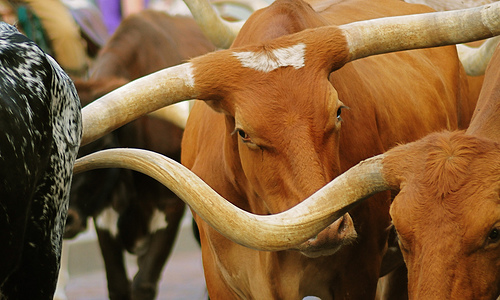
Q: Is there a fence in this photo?
A: No, there are no fences.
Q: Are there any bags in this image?
A: No, there are no bags.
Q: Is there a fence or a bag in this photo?
A: No, there are no bags or fences.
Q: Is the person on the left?
A: Yes, the person is on the left of the image.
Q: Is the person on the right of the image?
A: No, the person is on the left of the image.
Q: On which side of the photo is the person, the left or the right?
A: The person is on the left of the image.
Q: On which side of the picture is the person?
A: The person is on the left of the image.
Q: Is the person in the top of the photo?
A: Yes, the person is in the top of the image.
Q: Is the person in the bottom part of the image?
A: No, the person is in the top of the image.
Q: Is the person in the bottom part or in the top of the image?
A: The person is in the top of the image.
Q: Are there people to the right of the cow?
A: No, the person is to the left of the cow.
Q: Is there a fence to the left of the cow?
A: No, there is a person to the left of the cow.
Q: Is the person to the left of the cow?
A: Yes, the person is to the left of the cow.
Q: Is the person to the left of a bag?
A: No, the person is to the left of the cow.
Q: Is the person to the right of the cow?
A: No, the person is to the left of the cow.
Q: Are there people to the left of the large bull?
A: Yes, there is a person to the left of the bull.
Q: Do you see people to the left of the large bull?
A: Yes, there is a person to the left of the bull.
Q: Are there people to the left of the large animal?
A: Yes, there is a person to the left of the bull.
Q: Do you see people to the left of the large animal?
A: Yes, there is a person to the left of the bull.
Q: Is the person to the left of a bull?
A: Yes, the person is to the left of a bull.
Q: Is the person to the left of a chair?
A: No, the person is to the left of a bull.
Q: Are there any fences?
A: No, there are no fences.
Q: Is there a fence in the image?
A: No, there are no fences.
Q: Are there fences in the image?
A: No, there are no fences.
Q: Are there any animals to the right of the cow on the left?
A: No, the animal is to the left of the cow.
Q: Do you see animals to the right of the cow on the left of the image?
A: No, the animal is to the left of the cow.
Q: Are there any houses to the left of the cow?
A: No, there is an animal to the left of the cow.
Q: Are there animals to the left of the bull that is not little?
A: Yes, there is an animal to the left of the bull.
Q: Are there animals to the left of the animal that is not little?
A: Yes, there is an animal to the left of the bull.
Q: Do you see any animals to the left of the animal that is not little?
A: Yes, there is an animal to the left of the bull.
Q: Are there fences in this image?
A: No, there are no fences.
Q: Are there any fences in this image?
A: No, there are no fences.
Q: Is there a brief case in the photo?
A: No, there are no briefcases.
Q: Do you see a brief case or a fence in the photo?
A: No, there are no briefcases or fences.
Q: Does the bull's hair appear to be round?
A: Yes, the hair is round.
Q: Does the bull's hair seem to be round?
A: Yes, the hair is round.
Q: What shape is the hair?
A: The hair is round.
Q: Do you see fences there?
A: No, there are no fences.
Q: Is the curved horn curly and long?
A: Yes, the horn is curly and long.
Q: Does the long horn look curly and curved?
A: Yes, the horn is curly and curved.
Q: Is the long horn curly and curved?
A: Yes, the horn is curly and curved.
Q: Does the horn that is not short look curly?
A: Yes, the horn is curly.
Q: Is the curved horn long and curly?
A: Yes, the horn is long and curly.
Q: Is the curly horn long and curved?
A: Yes, the horn is long and curved.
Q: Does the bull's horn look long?
A: Yes, the horn is long.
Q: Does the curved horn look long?
A: Yes, the horn is long.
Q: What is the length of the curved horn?
A: The horn is long.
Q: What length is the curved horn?
A: The horn is long.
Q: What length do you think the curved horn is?
A: The horn is long.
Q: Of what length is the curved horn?
A: The horn is long.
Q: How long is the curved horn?
A: The horn is long.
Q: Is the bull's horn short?
A: No, the horn is long.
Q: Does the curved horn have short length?
A: No, the horn is long.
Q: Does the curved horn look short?
A: No, the horn is long.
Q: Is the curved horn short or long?
A: The horn is long.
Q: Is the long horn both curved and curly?
A: Yes, the horn is curved and curly.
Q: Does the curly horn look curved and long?
A: Yes, the horn is curved and long.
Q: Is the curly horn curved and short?
A: No, the horn is curved but long.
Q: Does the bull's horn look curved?
A: Yes, the horn is curved.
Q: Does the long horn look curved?
A: Yes, the horn is curved.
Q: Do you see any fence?
A: No, there are no fences.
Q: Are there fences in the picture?
A: No, there are no fences.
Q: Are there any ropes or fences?
A: No, there are no fences or ropes.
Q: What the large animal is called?
A: The animal is a bull.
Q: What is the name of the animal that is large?
A: The animal is a bull.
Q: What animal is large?
A: The animal is a bull.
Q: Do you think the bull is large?
A: Yes, the bull is large.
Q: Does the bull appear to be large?
A: Yes, the bull is large.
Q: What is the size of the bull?
A: The bull is large.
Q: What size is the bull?
A: The bull is large.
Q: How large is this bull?
A: The bull is large.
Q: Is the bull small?
A: No, the bull is large.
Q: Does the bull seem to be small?
A: No, the bull is large.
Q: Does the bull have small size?
A: No, the bull is large.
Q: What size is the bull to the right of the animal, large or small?
A: The bull is large.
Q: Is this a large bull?
A: Yes, this is a large bull.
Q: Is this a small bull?
A: No, this is a large bull.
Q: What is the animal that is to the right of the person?
A: The animal is a bull.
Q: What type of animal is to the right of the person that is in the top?
A: The animal is a bull.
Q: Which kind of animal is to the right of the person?
A: The animal is a bull.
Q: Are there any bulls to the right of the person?
A: Yes, there is a bull to the right of the person.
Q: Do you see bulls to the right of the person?
A: Yes, there is a bull to the right of the person.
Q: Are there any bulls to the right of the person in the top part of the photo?
A: Yes, there is a bull to the right of the person.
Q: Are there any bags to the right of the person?
A: No, there is a bull to the right of the person.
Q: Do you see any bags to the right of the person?
A: No, there is a bull to the right of the person.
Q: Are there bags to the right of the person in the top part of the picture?
A: No, there is a bull to the right of the person.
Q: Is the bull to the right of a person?
A: Yes, the bull is to the right of a person.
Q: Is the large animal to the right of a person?
A: Yes, the bull is to the right of a person.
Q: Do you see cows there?
A: Yes, there is a cow.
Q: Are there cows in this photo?
A: Yes, there is a cow.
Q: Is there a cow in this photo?
A: Yes, there is a cow.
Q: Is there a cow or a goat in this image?
A: Yes, there is a cow.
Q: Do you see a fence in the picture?
A: No, there are no fences.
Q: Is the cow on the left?
A: Yes, the cow is on the left of the image.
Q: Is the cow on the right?
A: No, the cow is on the left of the image.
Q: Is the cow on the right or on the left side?
A: The cow is on the left of the image.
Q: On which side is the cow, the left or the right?
A: The cow is on the left of the image.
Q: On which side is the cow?
A: The cow is on the left of the image.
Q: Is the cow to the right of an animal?
A: Yes, the cow is to the right of an animal.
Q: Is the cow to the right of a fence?
A: No, the cow is to the right of an animal.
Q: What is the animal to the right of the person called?
A: The animal is a cow.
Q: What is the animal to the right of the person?
A: The animal is a cow.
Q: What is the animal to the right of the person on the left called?
A: The animal is a cow.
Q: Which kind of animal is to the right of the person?
A: The animal is a cow.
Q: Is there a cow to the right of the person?
A: Yes, there is a cow to the right of the person.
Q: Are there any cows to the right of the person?
A: Yes, there is a cow to the right of the person.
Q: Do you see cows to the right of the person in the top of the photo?
A: Yes, there is a cow to the right of the person.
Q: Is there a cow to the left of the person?
A: No, the cow is to the right of the person.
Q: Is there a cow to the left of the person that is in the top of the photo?
A: No, the cow is to the right of the person.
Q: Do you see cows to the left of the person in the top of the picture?
A: No, the cow is to the right of the person.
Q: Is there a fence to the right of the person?
A: No, there is a cow to the right of the person.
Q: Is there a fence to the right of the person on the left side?
A: No, there is a cow to the right of the person.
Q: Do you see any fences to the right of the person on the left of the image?
A: No, there is a cow to the right of the person.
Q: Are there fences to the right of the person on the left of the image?
A: No, there is a cow to the right of the person.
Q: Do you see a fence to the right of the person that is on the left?
A: No, there is a cow to the right of the person.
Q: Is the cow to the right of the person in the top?
A: Yes, the cow is to the right of the person.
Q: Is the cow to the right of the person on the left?
A: Yes, the cow is to the right of the person.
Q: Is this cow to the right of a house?
A: No, the cow is to the right of the person.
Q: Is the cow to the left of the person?
A: No, the cow is to the right of the person.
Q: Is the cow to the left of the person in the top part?
A: No, the cow is to the right of the person.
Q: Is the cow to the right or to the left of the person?
A: The cow is to the right of the person.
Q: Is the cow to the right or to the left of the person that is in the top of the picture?
A: The cow is to the right of the person.